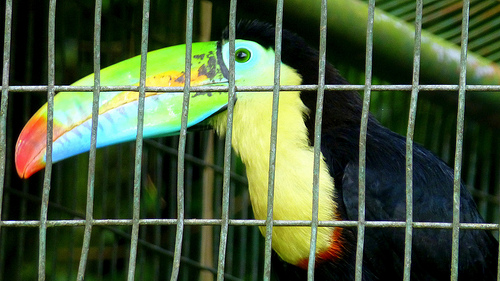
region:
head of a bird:
[1, 37, 303, 169]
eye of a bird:
[224, 32, 254, 82]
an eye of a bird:
[224, 43, 256, 66]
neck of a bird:
[187, 68, 354, 225]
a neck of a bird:
[209, 37, 369, 223]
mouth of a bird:
[22, 50, 194, 216]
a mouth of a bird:
[17, 45, 214, 199]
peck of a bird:
[20, 34, 245, 261]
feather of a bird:
[340, 180, 365, 202]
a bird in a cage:
[59, 41, 376, 271]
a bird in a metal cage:
[28, 8, 395, 272]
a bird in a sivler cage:
[47, 45, 457, 271]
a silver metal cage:
[65, 38, 427, 268]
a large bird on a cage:
[53, 21, 493, 251]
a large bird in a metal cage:
[7, 21, 451, 277]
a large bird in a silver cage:
[57, 33, 404, 260]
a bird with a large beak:
[50, 36, 407, 241]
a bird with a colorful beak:
[57, 13, 494, 242]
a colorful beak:
[19, 49, 294, 131]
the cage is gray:
[211, 209, 276, 247]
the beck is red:
[18, 149, 32, 163]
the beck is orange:
[31, 119, 49, 131]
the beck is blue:
[62, 105, 79, 117]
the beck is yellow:
[156, 75, 178, 87]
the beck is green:
[153, 53, 172, 67]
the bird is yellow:
[247, 117, 268, 143]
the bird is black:
[333, 119, 354, 145]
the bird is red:
[328, 234, 342, 257]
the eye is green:
[235, 46, 252, 64]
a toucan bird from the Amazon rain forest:
[14, 36, 499, 280]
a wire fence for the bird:
[360, 0, 495, 275]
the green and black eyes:
[230, 45, 245, 60]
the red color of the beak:
[10, 110, 60, 175]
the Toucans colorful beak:
[10, 40, 220, 175]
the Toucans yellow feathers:
[206, 111, 331, 261]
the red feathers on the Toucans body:
[296, 210, 342, 270]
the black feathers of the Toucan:
[337, 80, 497, 278]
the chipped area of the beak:
[191, 50, 216, 80]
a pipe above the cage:
[363, 0, 499, 98]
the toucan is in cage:
[3, 28, 492, 278]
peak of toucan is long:
[11, 28, 225, 185]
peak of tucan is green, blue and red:
[8, 37, 230, 187]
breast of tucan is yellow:
[216, 98, 328, 258]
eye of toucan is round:
[228, 43, 253, 71]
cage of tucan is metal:
[3, 4, 490, 276]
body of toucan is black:
[301, 80, 496, 280]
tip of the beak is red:
[12, 113, 56, 182]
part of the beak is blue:
[63, 107, 153, 152]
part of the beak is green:
[78, 37, 208, 83]